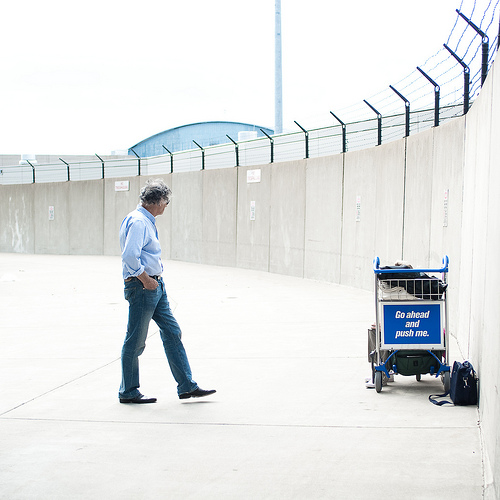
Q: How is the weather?
A: It is overcast.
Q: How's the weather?
A: It is overcast.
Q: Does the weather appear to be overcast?
A: Yes, it is overcast.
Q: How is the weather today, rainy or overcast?
A: It is overcast.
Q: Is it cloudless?
A: No, it is overcast.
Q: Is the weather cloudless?
A: No, it is overcast.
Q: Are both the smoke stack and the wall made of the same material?
A: Yes, both the smoke stack and the wall are made of cement.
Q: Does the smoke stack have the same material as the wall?
A: Yes, both the smoke stack and the wall are made of cement.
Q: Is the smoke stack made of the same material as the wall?
A: Yes, both the smoke stack and the wall are made of cement.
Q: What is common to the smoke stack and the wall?
A: The material, both the smoke stack and the wall are concrete.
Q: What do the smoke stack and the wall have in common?
A: The material, both the smoke stack and the wall are concrete.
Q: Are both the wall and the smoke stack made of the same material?
A: Yes, both the wall and the smoke stack are made of concrete.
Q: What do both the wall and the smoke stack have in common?
A: The material, both the wall and the smoke stack are concrete.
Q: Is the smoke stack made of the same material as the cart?
A: No, the smoke stack is made of concrete and the cart is made of metal.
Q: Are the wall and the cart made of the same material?
A: No, the wall is made of cement and the cart is made of metal.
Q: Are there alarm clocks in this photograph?
A: No, there are no alarm clocks.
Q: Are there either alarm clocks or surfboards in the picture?
A: No, there are no alarm clocks or surfboards.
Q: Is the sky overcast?
A: Yes, the sky is overcast.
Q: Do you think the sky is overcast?
A: Yes, the sky is overcast.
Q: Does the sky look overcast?
A: Yes, the sky is overcast.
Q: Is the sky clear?
A: No, the sky is overcast.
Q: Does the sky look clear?
A: No, the sky is overcast.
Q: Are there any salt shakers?
A: No, there are no salt shakers.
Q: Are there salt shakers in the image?
A: No, there are no salt shakers.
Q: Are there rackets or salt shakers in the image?
A: No, there are no salt shakers or rackets.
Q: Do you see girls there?
A: No, there are no girls.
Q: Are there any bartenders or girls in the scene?
A: No, there are no girls or bartenders.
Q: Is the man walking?
A: Yes, the man is walking.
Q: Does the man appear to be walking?
A: Yes, the man is walking.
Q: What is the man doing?
A: The man is walking.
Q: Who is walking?
A: The man is walking.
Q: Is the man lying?
A: No, the man is walking.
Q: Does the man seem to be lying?
A: No, the man is walking.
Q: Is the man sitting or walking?
A: The man is walking.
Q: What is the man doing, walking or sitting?
A: The man is walking.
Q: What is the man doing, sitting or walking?
A: The man is walking.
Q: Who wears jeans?
A: The man wears jeans.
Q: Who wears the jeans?
A: The man wears jeans.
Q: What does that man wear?
A: The man wears jeans.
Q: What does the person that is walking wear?
A: The man wears jeans.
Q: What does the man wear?
A: The man wears jeans.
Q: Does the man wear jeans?
A: Yes, the man wears jeans.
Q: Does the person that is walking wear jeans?
A: Yes, the man wears jeans.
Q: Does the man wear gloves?
A: No, the man wears jeans.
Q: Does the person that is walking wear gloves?
A: No, the man wears jeans.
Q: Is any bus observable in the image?
A: No, there are no buses.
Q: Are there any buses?
A: No, there are no buses.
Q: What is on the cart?
A: The sign is on the cart.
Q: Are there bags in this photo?
A: Yes, there is a bag.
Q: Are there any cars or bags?
A: Yes, there is a bag.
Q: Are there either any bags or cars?
A: Yes, there is a bag.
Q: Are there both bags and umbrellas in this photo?
A: No, there is a bag but no umbrellas.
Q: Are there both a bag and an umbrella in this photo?
A: No, there is a bag but no umbrellas.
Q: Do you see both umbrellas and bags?
A: No, there is a bag but no umbrellas.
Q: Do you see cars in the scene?
A: No, there are no cars.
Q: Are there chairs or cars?
A: No, there are no cars or chairs.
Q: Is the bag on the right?
A: Yes, the bag is on the right of the image.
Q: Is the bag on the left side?
A: No, the bag is on the right of the image.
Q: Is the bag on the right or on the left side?
A: The bag is on the right of the image.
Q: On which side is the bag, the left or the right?
A: The bag is on the right of the image.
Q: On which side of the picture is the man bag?
A: The bag is on the right of the image.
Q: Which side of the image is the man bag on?
A: The bag is on the right of the image.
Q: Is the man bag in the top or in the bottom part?
A: The bag is in the bottom of the image.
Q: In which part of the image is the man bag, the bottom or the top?
A: The bag is in the bottom of the image.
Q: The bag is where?
A: The bag is on the ground.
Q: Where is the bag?
A: The bag is on the ground.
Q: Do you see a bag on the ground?
A: Yes, there is a bag on the ground.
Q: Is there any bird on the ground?
A: No, there is a bag on the ground.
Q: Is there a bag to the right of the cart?
A: Yes, there is a bag to the right of the cart.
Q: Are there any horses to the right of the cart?
A: No, there is a bag to the right of the cart.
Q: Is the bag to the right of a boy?
A: No, the bag is to the right of the cart.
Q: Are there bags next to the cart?
A: Yes, there is a bag next to the cart.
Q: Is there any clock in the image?
A: No, there are no clocks.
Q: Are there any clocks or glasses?
A: No, there are no clocks or glasses.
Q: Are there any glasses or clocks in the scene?
A: No, there are no clocks or glasses.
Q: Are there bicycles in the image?
A: No, there are no bicycles.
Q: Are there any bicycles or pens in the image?
A: No, there are no bicycles or pens.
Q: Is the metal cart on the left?
A: No, the cart is on the right of the image.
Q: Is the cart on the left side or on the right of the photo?
A: The cart is on the right of the image.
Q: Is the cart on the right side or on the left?
A: The cart is on the right of the image.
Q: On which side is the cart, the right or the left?
A: The cart is on the right of the image.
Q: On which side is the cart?
A: The cart is on the right of the image.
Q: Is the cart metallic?
A: Yes, the cart is metallic.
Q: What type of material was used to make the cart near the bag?
A: The cart is made of metal.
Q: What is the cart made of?
A: The cart is made of metal.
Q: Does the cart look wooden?
A: No, the cart is metallic.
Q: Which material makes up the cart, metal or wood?
A: The cart is made of metal.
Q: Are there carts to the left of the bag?
A: Yes, there is a cart to the left of the bag.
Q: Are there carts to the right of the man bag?
A: No, the cart is to the left of the bag.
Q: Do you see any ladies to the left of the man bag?
A: No, there is a cart to the left of the bag.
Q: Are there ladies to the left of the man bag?
A: No, there is a cart to the left of the bag.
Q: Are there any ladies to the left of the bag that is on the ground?
A: No, there is a cart to the left of the bag.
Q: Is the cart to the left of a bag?
A: Yes, the cart is to the left of a bag.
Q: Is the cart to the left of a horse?
A: No, the cart is to the left of a bag.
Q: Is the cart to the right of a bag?
A: No, the cart is to the left of a bag.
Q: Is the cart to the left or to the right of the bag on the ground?
A: The cart is to the left of the bag.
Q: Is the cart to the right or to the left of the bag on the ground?
A: The cart is to the left of the bag.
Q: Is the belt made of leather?
A: Yes, the belt is made of leather.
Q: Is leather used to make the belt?
A: Yes, the belt is made of leather.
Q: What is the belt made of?
A: The belt is made of leather.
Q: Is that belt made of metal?
A: No, the belt is made of leather.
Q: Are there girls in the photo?
A: No, there are no girls.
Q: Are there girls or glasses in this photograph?
A: No, there are no girls or glasses.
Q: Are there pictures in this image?
A: No, there are no pictures.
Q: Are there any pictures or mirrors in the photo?
A: No, there are no pictures or mirrors.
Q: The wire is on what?
A: The wire is on the wall.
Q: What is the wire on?
A: The wire is on the wall.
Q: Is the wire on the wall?
A: Yes, the wire is on the wall.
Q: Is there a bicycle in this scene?
A: No, there are no bicycles.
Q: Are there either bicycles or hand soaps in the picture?
A: No, there are no bicycles or hand soaps.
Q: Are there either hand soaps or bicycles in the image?
A: No, there are no bicycles or hand soaps.